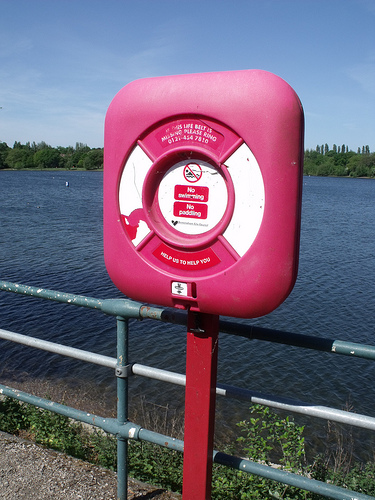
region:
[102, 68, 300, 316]
a no swimming sign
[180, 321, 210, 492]
a red metal stand for the sign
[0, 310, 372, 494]
the safety hand rails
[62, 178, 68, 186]
a waterway floating buoy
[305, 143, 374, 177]
large trees across the waterway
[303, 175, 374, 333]
dark water on the river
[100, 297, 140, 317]
the horizontal pole sleeve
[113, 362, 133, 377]
a grey pipe attachment coupler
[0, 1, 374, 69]
blue sky with minimal clouds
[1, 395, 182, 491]
weeds along the river bank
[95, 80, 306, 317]
large pink rounded sign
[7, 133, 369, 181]
line of wooded area across the lake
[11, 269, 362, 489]
blue metal fence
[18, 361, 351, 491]
grasses and weeds beside a lake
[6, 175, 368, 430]
blue lake with ripples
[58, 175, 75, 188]
small white object on the water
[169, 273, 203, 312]
white label with a slot beside it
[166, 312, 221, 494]
pink pole holding a pink sign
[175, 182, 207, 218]
two small signs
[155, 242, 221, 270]
pink curved box with white letters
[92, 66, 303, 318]
red square box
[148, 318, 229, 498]
red wooden post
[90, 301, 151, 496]
green metal fence pole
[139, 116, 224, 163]
white writing on sign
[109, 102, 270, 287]
circular diagram on sign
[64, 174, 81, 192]
small white boat in water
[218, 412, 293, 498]
green plants growing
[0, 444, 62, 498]
gravel terrain on ground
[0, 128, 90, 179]
green trees next to water line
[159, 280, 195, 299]
small white logo on bottom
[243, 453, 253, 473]
edge of a pole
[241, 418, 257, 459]
part of a lake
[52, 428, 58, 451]
edge of a bridge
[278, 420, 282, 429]
part of an ocean body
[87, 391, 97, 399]
part of a grass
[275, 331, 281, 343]
part of a shadow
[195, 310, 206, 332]
part of a floater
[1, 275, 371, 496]
the fence beside the water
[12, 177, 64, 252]
the water is calm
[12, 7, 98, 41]
the clear blue sky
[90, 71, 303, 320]
the life preserve on the pole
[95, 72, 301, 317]
the life preserver is pink and white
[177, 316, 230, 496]
the pole is red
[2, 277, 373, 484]
the fence is metal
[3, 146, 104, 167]
the trees with green leaves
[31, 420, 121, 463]
the plants beside the water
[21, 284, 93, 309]
the chipped paint on the fence